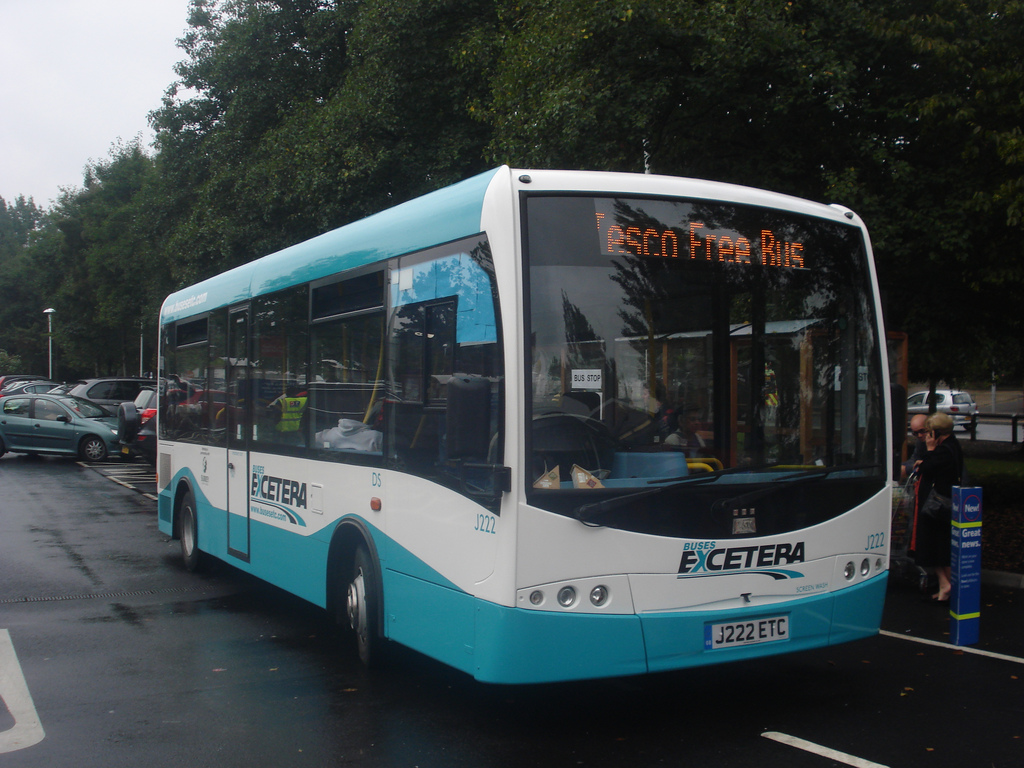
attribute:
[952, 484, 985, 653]
pole — blue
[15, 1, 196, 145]
sky — blue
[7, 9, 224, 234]
sky — blue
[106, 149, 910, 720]
transit bus — blue, white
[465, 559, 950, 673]
bumper — blue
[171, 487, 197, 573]
tire — rear tire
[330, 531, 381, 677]
tire — rear tire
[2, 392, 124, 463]
car — green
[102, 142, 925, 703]
bus — blue